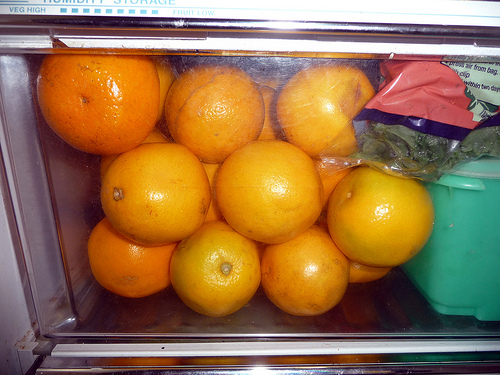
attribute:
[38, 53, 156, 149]
fruit — ORANGE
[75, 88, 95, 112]
spot — DARK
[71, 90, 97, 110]
spot — dark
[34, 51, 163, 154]
fruit — orange, ripe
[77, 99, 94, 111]
spot — dark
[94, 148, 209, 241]
fruit — ripe, orange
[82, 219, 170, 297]
fruit — orange, ripe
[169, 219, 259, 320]
fruit — ripe, orange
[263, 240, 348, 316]
fruit — orange, ripe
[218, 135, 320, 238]
fruit — ripe, orange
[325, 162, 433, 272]
fruit — orange, ripe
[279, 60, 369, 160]
fruit — ripe, orange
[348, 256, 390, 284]
fruit — orange, ripe